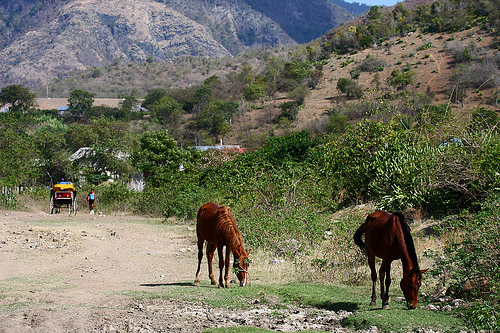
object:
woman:
[85, 187, 95, 212]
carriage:
[47, 180, 79, 216]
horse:
[191, 201, 255, 289]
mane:
[218, 212, 248, 256]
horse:
[351, 209, 429, 309]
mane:
[390, 210, 421, 277]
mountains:
[0, 1, 367, 101]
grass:
[276, 281, 464, 332]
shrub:
[334, 77, 362, 100]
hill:
[156, 0, 499, 300]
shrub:
[386, 69, 412, 92]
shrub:
[413, 44, 422, 52]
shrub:
[325, 109, 347, 135]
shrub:
[280, 101, 300, 121]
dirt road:
[2, 207, 286, 331]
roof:
[1, 95, 149, 110]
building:
[0, 97, 151, 117]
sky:
[339, 1, 400, 8]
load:
[54, 183, 74, 192]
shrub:
[355, 52, 384, 73]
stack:
[216, 139, 224, 146]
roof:
[187, 141, 239, 151]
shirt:
[89, 193, 96, 200]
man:
[59, 177, 66, 183]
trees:
[63, 89, 95, 122]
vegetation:
[306, 118, 407, 205]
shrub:
[272, 76, 296, 93]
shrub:
[208, 110, 231, 150]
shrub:
[422, 54, 429, 60]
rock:
[160, 273, 166, 278]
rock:
[106, 231, 116, 238]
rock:
[81, 256, 90, 259]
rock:
[75, 273, 85, 280]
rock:
[80, 233, 88, 238]